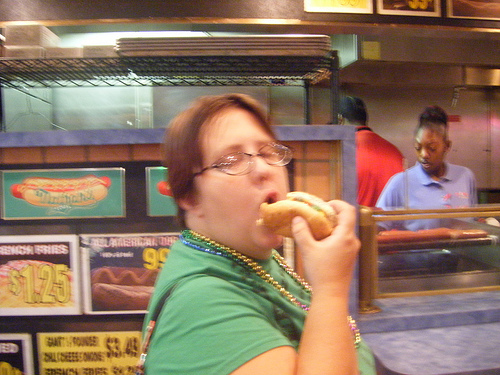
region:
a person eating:
[136, 89, 384, 374]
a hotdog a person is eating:
[251, 190, 339, 247]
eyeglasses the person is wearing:
[180, 139, 292, 177]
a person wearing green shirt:
[133, 89, 380, 373]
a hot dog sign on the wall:
[3, 167, 127, 220]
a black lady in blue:
[376, 102, 480, 280]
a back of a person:
[333, 90, 402, 209]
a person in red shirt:
[328, 91, 407, 217]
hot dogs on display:
[378, 222, 489, 242]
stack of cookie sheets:
[113, 33, 338, 65]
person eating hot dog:
[168, 103, 365, 295]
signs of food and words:
[30, 164, 162, 319]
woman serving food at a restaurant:
[400, 96, 463, 238]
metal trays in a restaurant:
[101, 23, 371, 65]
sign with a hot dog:
[11, 175, 145, 216]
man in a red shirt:
[326, 100, 400, 191]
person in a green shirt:
[138, 98, 364, 353]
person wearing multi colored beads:
[179, 125, 364, 372]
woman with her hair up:
[401, 81, 471, 181]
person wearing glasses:
[171, 91, 339, 213]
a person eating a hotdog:
[131, 64, 412, 361]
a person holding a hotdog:
[141, 56, 374, 361]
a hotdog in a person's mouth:
[162, 91, 370, 268]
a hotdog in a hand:
[255, 186, 380, 282]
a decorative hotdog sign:
[1, 166, 137, 230]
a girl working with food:
[345, 71, 499, 272]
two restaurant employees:
[331, 89, 496, 269]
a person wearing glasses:
[154, 86, 297, 294]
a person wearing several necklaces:
[117, 73, 380, 365]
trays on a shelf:
[14, 20, 343, 84]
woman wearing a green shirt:
[139, 231, 315, 359]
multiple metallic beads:
[211, 219, 296, 302]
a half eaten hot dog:
[257, 207, 337, 234]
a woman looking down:
[388, 119, 492, 212]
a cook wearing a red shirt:
[354, 93, 393, 205]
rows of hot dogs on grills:
[379, 229, 497, 261]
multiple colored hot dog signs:
[7, 169, 131, 358]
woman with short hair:
[173, 101, 297, 205]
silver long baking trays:
[113, 24, 351, 72]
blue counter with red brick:
[17, 138, 103, 167]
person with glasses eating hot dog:
[132, 89, 395, 369]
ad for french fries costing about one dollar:
[0, 240, 96, 338]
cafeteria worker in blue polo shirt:
[363, 89, 486, 285]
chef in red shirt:
[309, 71, 431, 229]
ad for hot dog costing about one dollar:
[70, 218, 187, 325]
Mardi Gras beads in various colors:
[158, 210, 389, 364]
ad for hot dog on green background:
[0, 160, 135, 231]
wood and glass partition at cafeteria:
[345, 191, 499, 303]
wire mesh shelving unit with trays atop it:
[0, 19, 350, 138]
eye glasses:
[178, 138, 305, 183]